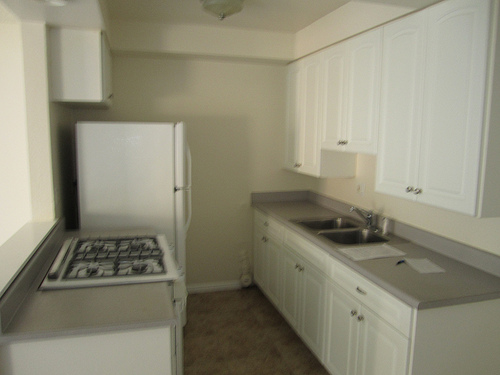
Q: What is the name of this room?
A: Kitchen.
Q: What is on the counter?
A: Paper.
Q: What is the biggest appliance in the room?
A: Refridgerator.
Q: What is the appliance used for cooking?
A: Stove.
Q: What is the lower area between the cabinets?
A: Floor.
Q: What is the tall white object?
A: Fridge.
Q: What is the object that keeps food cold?
A: Fridge.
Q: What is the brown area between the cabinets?
A: Floor.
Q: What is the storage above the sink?
A: Cabinets.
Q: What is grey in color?
A: The counter top.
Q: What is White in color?
A: The fridge.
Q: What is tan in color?
A: The floor.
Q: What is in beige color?
A: The back wall.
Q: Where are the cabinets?
A: On the wall.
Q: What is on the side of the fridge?
A: Cooking range.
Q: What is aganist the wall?
A: Gray kichten counter.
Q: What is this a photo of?
A: A kitchen.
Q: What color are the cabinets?
A: White.